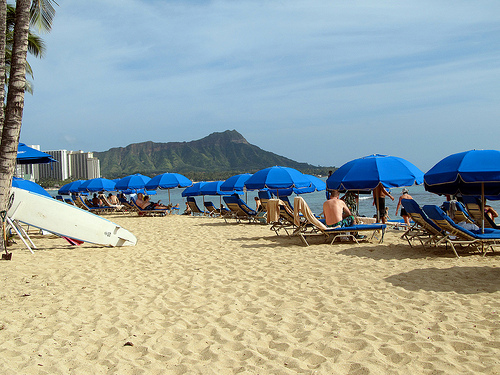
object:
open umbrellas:
[182, 144, 498, 201]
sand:
[0, 209, 498, 373]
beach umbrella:
[181, 183, 203, 197]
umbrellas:
[58, 149, 496, 197]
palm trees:
[0, 0, 64, 146]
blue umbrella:
[423, 149, 499, 197]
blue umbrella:
[323, 154, 428, 189]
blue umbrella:
[243, 165, 311, 189]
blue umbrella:
[220, 172, 253, 191]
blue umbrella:
[201, 181, 244, 195]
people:
[107, 193, 119, 205]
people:
[322, 190, 358, 225]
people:
[483, 204, 495, 222]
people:
[137, 193, 170, 210]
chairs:
[291, 197, 388, 244]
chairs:
[463, 195, 499, 232]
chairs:
[129, 197, 168, 212]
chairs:
[187, 196, 204, 213]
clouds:
[117, 51, 213, 92]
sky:
[54, 3, 491, 86]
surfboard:
[10, 187, 138, 247]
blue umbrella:
[145, 172, 194, 188]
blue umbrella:
[57, 180, 85, 194]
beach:
[0, 199, 499, 374]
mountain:
[105, 124, 331, 169]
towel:
[293, 196, 340, 230]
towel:
[266, 198, 293, 222]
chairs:
[265, 199, 294, 235]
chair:
[222, 196, 257, 215]